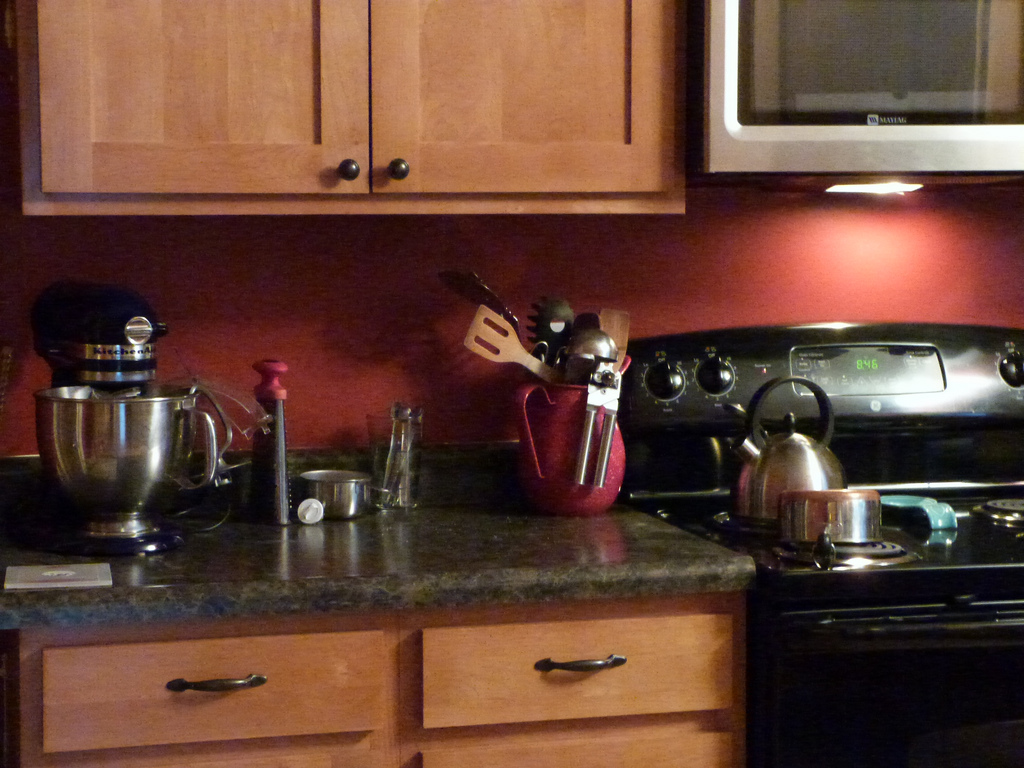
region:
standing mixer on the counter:
[33, 275, 221, 566]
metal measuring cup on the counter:
[301, 465, 382, 522]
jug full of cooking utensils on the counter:
[511, 375, 628, 521]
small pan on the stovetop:
[779, 487, 887, 567]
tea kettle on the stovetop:
[722, 373, 852, 523]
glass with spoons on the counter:
[365, 408, 424, 510]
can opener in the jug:
[576, 354, 625, 488]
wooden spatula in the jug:
[460, 304, 553, 377]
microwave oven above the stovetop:
[693, 0, 1022, 191]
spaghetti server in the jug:
[523, 290, 580, 358]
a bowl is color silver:
[21, 372, 190, 554]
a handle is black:
[530, 646, 638, 682]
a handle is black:
[152, 663, 269, 702]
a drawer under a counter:
[17, 627, 406, 763]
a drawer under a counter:
[402, 596, 753, 752]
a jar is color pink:
[502, 337, 646, 527]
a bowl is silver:
[293, 453, 383, 531]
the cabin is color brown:
[10, 3, 699, 244]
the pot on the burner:
[770, 479, 901, 571]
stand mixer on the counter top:
[19, 274, 220, 563]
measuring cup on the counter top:
[296, 463, 389, 524]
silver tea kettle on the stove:
[721, 371, 846, 533]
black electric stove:
[619, 319, 1018, 760]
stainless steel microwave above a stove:
[695, 0, 1022, 187]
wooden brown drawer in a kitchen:
[420, 611, 743, 735]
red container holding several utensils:
[429, 261, 629, 524]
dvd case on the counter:
[2, 562, 120, 594]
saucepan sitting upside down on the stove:
[768, 485, 879, 577]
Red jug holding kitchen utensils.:
[466, 281, 650, 525]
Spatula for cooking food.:
[457, 306, 560, 389]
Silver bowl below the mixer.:
[43, 367, 221, 549]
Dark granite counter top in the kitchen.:
[425, 521, 697, 601]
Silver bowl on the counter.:
[296, 451, 392, 521]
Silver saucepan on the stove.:
[773, 483, 895, 586]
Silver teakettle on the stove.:
[703, 341, 852, 535]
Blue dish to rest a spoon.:
[877, 481, 972, 543]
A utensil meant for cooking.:
[527, 286, 570, 357]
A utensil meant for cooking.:
[563, 323, 614, 366]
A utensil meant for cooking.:
[575, 314, 592, 335]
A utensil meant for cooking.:
[597, 307, 636, 369]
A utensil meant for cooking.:
[470, 311, 554, 384]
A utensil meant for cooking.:
[445, 270, 543, 359]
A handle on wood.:
[525, 646, 624, 672]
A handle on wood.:
[164, 669, 273, 699]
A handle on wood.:
[332, 156, 364, 183]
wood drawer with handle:
[393, 601, 760, 750]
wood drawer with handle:
[387, 569, 773, 741]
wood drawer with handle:
[438, 576, 770, 700]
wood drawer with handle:
[393, 575, 745, 750]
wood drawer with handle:
[387, 559, 752, 757]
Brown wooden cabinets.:
[15, 6, 728, 765]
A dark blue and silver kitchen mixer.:
[34, 279, 221, 565]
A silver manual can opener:
[570, 345, 622, 511]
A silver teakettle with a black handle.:
[723, 361, 864, 538]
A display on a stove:
[782, 342, 944, 401]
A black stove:
[618, 327, 1018, 765]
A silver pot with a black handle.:
[775, 484, 893, 564]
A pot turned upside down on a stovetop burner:
[777, 474, 899, 573]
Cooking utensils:
[431, 248, 666, 539]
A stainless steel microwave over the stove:
[697, 7, 1020, 201]